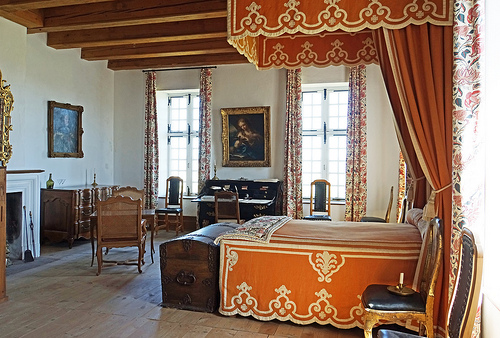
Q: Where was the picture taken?
A: In a bedroom.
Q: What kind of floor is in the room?
A: Wood.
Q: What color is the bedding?
A: Orange.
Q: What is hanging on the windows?
A: Curtains.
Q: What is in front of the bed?
A: A trunk.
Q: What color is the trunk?
A: Brown.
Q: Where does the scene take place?
A: In a bedroom.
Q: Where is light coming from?
A: Windows.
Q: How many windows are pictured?
A: Two.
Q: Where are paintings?
A: On the wall.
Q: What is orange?
A: Bed curtains.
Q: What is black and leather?
A: Chair seat.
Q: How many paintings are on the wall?
A: Two.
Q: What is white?
A: Walls.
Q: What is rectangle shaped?
A: The windows.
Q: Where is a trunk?
A: On the floor.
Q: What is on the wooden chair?
A: Candlestick.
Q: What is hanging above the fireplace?
A: A gilded frame.